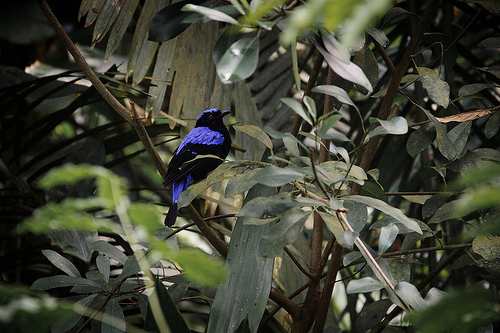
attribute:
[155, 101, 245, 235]
bird — blue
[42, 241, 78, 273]
leaf — green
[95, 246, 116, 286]
leaf — green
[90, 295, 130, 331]
leaf — green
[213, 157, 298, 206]
leaf — green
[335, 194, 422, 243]
leaf — green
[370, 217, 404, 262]
leaf — green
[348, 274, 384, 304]
leaf — green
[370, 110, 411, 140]
leaf — green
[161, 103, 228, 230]
bird — blue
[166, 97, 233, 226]
bird — blue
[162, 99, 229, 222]
bird — blue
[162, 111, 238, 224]
bird — blue, black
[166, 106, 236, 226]
bird — blue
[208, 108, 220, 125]
eye — red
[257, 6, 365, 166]
leaves — green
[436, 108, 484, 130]
leaf — brown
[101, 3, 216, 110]
leaves — elongated, green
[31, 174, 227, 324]
leaves — green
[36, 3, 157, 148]
branch — tree branch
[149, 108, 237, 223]
bird — small, black, blue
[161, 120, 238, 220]
bird — black, blue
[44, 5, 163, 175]
branch — tree branch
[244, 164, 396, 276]
leaves — green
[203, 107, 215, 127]
eye — bird's eye, red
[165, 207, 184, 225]
feather — black, tail feather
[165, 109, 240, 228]
bird — black, blue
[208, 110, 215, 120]
eye — red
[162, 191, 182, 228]
feather — tail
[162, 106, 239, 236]
bird — blue, black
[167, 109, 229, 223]
bird — black, blue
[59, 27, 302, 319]
branch — thin, brown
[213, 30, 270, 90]
leaf — wet, green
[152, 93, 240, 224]
bird — black, blue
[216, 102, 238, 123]
beak — black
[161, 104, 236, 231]
bird — black, blue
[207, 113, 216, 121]
eye — small, red